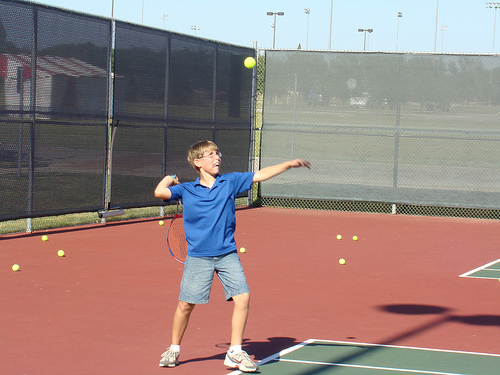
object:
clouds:
[372, 16, 427, 50]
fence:
[3, 2, 498, 233]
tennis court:
[0, 0, 499, 375]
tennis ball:
[339, 258, 345, 265]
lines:
[279, 358, 345, 369]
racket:
[165, 173, 187, 262]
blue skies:
[1, 0, 499, 375]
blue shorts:
[177, 251, 248, 305]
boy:
[152, 139, 311, 373]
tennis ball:
[243, 57, 255, 69]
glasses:
[201, 150, 223, 157]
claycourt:
[1, 204, 499, 373]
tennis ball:
[41, 235, 49, 242]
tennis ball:
[239, 247, 246, 253]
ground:
[0, 204, 499, 374]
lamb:
[171, 168, 256, 273]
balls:
[57, 250, 67, 258]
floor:
[0, 201, 500, 375]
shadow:
[177, 332, 372, 373]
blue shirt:
[166, 170, 256, 256]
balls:
[11, 263, 21, 273]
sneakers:
[157, 345, 186, 367]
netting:
[240, 45, 499, 208]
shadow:
[348, 329, 356, 345]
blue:
[186, 207, 226, 244]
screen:
[0, 51, 124, 116]